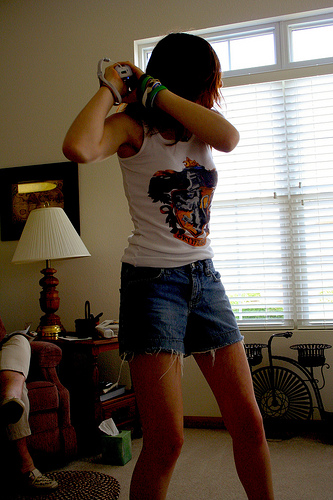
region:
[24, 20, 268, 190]
girl holding a remote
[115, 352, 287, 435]
legs of the girl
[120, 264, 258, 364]
shorts of the girl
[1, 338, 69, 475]
crossed legs in background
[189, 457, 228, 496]
floor in the room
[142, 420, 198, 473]
knee of the person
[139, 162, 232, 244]
design on the shirt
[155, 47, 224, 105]
hair on the lady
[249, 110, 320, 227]
blinds on the window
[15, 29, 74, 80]
white wall next to people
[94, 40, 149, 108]
girl is holding a wii remote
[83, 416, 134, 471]
tissue box on the floor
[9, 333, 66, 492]
woman has her legs crossed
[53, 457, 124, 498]
rug on the floor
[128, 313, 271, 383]
girl's short has strings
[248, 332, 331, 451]
bike decoration under the window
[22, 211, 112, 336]
lamp on side table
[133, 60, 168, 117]
girl is wearing several bracelets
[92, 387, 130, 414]
book on shelf of table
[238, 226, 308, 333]
blind slats are open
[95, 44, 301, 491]
a young woman playing a video game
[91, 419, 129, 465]
a green box with white tissues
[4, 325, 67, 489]
a person sitting on the sofa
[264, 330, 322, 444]
an old fashioned decorative bicycle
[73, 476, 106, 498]
a multicolored braided rug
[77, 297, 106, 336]
a dark colored basket on the table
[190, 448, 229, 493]
beige carpet on the floor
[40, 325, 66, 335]
a brass base on a lamp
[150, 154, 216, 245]
a colorful logo on a shirt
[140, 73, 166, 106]
bracelets on an arm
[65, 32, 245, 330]
a woman playing an interactive video game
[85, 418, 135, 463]
a green box of tissue on the floor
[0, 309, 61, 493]
person sitting in an armchair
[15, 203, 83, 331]
a lamp on a table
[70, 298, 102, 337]
a black basket on a table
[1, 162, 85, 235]
a poster on the wall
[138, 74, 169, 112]
a bunch of bracelets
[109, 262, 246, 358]
woman wearing jean shorts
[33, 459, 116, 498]
a round rug on the floor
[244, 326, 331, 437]
a metal black plant holder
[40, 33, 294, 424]
the woman is playing a video game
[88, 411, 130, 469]
a tissue box on the floor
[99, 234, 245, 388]
the woman is wearing jean shorts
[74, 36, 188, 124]
the woman is holding a wii remote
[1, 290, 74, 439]
a person is sitting on the couch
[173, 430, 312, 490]
the rug is beige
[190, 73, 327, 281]
the blinds are white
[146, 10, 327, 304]
the sun is coming in the window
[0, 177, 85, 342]
the table lamp is off